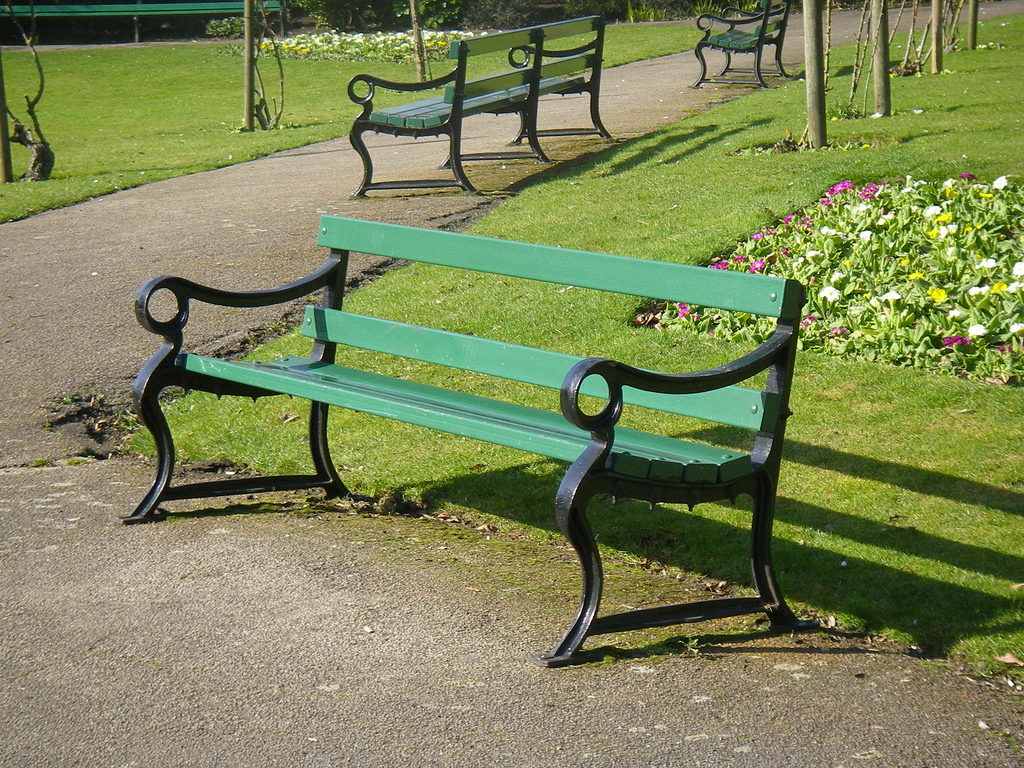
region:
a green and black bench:
[110, 196, 799, 636]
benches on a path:
[302, 8, 821, 189]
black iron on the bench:
[549, 345, 810, 669]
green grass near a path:
[479, 178, 713, 248]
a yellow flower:
[925, 283, 957, 313]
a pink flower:
[823, 169, 861, 202]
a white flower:
[956, 314, 994, 352]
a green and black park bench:
[130, 211, 802, 665]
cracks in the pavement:
[8, 386, 104, 510]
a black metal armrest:
[558, 329, 802, 503]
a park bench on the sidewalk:
[334, 15, 611, 225]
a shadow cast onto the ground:
[466, 404, 1021, 648]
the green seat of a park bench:
[178, 222, 768, 444]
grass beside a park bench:
[143, 383, 782, 628]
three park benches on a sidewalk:
[124, 15, 824, 649]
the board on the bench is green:
[360, 314, 484, 372]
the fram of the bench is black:
[563, 348, 666, 456]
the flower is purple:
[822, 174, 864, 206]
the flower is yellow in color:
[890, 253, 935, 292]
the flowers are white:
[345, 26, 378, 55]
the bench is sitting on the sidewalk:
[110, 456, 629, 695]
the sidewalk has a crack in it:
[21, 430, 114, 484]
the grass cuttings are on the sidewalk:
[375, 500, 524, 580]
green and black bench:
[79, 183, 807, 706]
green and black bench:
[337, 12, 628, 178]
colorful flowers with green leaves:
[890, 300, 958, 348]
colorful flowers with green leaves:
[802, 230, 860, 278]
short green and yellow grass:
[869, 467, 953, 544]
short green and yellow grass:
[802, 388, 847, 440]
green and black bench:
[152, 195, 807, 674]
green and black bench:
[353, 18, 630, 193]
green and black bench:
[667, 6, 789, 101]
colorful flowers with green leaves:
[831, 180, 866, 222]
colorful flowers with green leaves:
[860, 279, 928, 334]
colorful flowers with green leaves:
[903, 217, 965, 257]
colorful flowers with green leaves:
[936, 279, 988, 331]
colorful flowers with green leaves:
[824, 212, 894, 279]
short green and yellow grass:
[862, 476, 917, 525]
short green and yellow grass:
[827, 388, 900, 474]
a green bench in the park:
[106, 220, 860, 540]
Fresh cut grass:
[501, 117, 672, 282]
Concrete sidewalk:
[100, 594, 521, 759]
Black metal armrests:
[446, 344, 816, 733]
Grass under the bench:
[435, 115, 585, 207]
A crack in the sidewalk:
[3, 404, 111, 506]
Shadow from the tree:
[51, 116, 185, 235]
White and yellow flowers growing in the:
[245, 26, 452, 81]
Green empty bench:
[110, 208, 816, 676]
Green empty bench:
[343, 9, 619, 202]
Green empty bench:
[689, 2, 792, 94]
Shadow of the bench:
[381, 410, 1023, 666]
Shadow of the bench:
[487, 113, 785, 187]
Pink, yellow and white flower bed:
[632, 165, 1022, 407]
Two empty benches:
[344, 0, 804, 206]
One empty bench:
[122, 208, 837, 668]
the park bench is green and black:
[119, 211, 818, 670]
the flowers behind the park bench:
[136, 170, 1021, 667]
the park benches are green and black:
[133, 0, 814, 671]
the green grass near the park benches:
[0, 2, 1021, 767]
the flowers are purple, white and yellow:
[633, 168, 1022, 390]